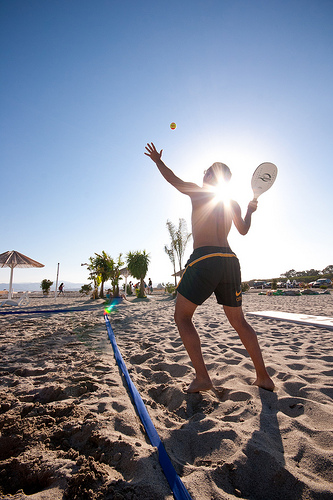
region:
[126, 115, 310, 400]
a guy with a paddle in hand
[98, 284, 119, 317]
a sun prism glare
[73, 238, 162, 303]
a small group of trees on the beach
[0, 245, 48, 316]
a straw umbrella on the beach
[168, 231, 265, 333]
yellow and black shorts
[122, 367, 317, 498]
shadow on ground from guy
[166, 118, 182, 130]
a yellow and orange ball in air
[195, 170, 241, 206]
sun rays coming over the shoulder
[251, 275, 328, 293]
cars parked along the edge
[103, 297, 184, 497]
a blue line in the sand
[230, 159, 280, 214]
Person holding a tennis racket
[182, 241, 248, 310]
Man wearing black shorts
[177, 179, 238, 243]
Man without a shirt on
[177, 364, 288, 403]
Man barefoot in the sand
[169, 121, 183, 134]
ball in the sky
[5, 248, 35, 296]
Umbrella on the beach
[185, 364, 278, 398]
Man without shoes on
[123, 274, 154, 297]
People on the beach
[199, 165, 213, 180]
Man wearing glasses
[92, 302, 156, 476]
Blue strap in the sand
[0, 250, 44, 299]
umbrella is open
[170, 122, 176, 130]
small yellow ball in front of blue sky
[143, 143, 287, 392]
man holding a white paddle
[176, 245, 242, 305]
man wearing black shorts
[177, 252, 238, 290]
yellow stripe on shorts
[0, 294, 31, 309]
white chair underneath umbrella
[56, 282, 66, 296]
person is walking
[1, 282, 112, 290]
blue water beneath sky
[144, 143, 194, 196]
arm is outstretched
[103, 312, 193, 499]
blue ribbon on top of the sand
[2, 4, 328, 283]
blue of daytime sky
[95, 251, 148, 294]
leaves on palm trees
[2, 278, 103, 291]
hazy mountain on horizon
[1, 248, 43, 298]
open umbrella on pole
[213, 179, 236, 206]
sun shining in sky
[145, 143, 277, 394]
boy with paddle in hand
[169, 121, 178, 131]
ball in mid air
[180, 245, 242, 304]
yellow stripes on shorts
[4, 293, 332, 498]
foot prints on beach sand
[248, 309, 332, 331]
white rectangle on sand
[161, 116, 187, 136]
A ball in the air.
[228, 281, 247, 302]
Nike logo on the back of the shorts.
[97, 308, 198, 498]
Blue rope on the ground.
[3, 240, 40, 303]
An umbrella on the side.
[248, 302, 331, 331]
A white board on the ground.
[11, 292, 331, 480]
The sand is brown.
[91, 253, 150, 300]
An umbrella behind the trees.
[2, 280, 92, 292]
Water in the background.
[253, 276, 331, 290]
Cars on the side.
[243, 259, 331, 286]
Trees in the background.